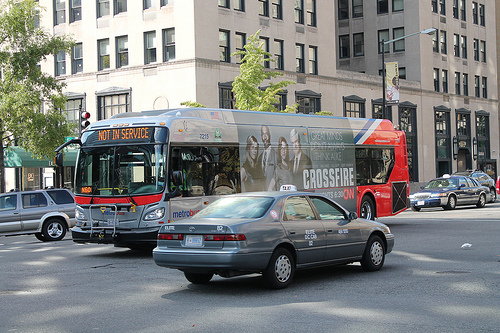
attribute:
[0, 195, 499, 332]
street — paved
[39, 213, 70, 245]
tire — round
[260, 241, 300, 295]
tire — round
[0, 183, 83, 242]
vehicle — silver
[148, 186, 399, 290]
car — gray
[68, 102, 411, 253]
bus — moving, long, multi-colored, out of service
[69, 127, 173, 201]
windshield — clean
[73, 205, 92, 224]
headlight — off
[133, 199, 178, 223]
headlight — off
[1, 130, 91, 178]
awning — green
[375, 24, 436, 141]
streetlamp — tall, off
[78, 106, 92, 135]
light — red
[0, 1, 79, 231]
tree — tall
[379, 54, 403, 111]
banner — rectangular